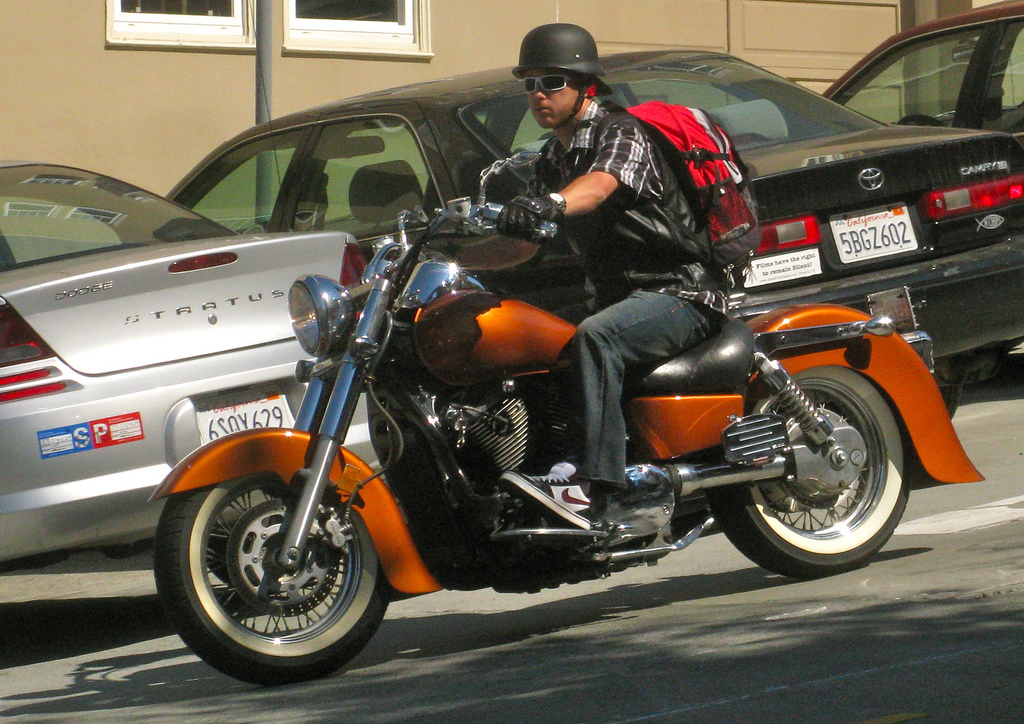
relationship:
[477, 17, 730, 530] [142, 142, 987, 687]
man riding motorcycle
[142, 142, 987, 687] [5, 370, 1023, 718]
motorcycle on street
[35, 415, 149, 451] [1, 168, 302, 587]
sticker on car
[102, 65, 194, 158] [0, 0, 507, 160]
wall on building